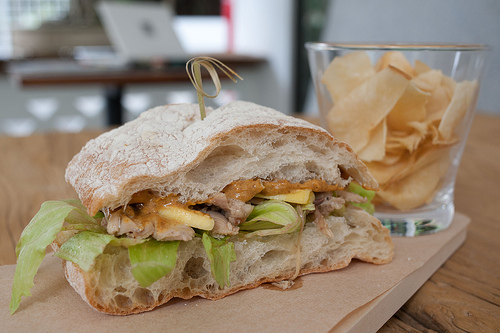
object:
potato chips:
[326, 52, 412, 163]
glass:
[304, 42, 489, 236]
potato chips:
[386, 83, 431, 130]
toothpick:
[183, 56, 244, 122]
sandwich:
[9, 100, 397, 317]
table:
[0, 110, 499, 332]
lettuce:
[127, 238, 180, 287]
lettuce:
[53, 230, 115, 273]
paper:
[2, 210, 470, 332]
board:
[0, 212, 468, 333]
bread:
[61, 205, 395, 317]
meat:
[144, 213, 194, 242]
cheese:
[159, 205, 217, 232]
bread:
[63, 99, 383, 216]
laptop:
[71, 2, 192, 69]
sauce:
[221, 179, 265, 202]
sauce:
[126, 194, 173, 225]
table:
[20, 56, 275, 128]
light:
[25, 98, 59, 122]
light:
[76, 94, 105, 116]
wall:
[2, 2, 297, 134]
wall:
[305, 2, 500, 113]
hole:
[259, 248, 291, 266]